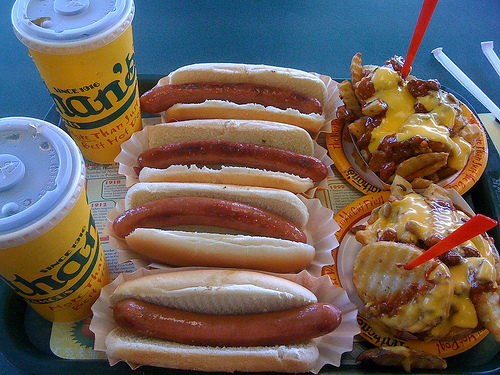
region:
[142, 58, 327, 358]
four hotdogs in buns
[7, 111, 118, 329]
yellow cup with green writing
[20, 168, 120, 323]
red writing on yellow cup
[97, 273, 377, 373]
hotdog and bun in white holder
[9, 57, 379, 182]
food and drinks on tray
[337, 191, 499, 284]
red plastic fork in food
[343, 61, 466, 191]
cheese and chili fries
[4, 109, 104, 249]
plastic lid on cup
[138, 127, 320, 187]
grill marks on hotdog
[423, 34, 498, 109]
straw wrapper next to food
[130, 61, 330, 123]
Hot dog on white plastic paper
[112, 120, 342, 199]
Hot dog on white plastic paper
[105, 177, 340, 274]
Hot dog on white plastic paper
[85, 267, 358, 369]
Hot dog on white plastic paper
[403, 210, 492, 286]
Red spoon in fry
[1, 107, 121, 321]
Beverage bottle in front of hot dog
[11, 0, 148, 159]
Beverage bottle in front of hot dog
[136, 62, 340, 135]
Hot dog on blue tray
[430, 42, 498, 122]
Straw next to straw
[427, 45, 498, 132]
Straw next to blue tray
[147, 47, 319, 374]
Hotdogs on a trey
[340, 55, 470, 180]
Chilli sheese fries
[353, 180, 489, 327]
Potatoe slices with chili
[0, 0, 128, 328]
Two yellow cups on the trey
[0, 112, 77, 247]
The plastic lid on the cup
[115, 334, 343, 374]
The bun for the hot dog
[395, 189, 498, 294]
A red fork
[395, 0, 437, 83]
A fork in the fries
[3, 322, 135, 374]
The green tray with a paper on it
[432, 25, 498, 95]
The straw on the table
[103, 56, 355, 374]
Hot dogs in the foreground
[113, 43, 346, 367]
Four hot dogs are on the tray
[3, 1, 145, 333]
Two soft drinks in plastic cups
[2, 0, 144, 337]
Plastic cups are yellow in color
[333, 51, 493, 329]
Food is covered in cheese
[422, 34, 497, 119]
Drinking straws in the background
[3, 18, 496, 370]
Tray is on the table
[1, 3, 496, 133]
The table is blue in color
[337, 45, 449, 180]
Fries are covered in cheese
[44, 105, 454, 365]
A menu paper is under the food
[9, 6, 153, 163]
the yellow covered cup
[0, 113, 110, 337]
the yellow covered cup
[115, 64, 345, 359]
the hot dogs on the tray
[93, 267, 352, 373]
the hot dog on the tray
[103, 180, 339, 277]
the hot dog on the tray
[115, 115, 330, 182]
the hot dog on the tray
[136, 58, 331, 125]
the hot dog on the tray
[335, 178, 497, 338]
the cheese covered fries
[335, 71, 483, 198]
the cheese covered fries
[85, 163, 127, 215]
the paper under the tray